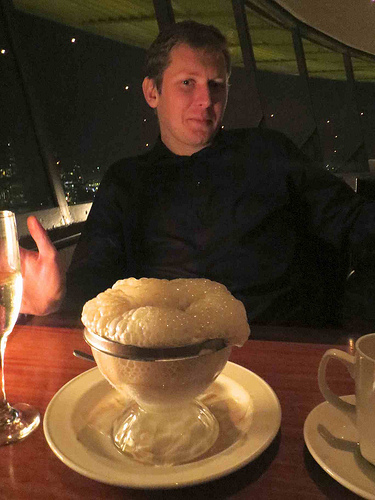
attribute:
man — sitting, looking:
[61, 16, 373, 327]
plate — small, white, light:
[304, 387, 374, 499]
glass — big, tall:
[0, 209, 44, 446]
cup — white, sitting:
[314, 332, 374, 463]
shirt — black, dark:
[59, 123, 372, 327]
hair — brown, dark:
[140, 19, 231, 92]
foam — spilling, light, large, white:
[75, 274, 250, 357]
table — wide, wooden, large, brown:
[2, 307, 371, 496]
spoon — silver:
[71, 347, 92, 367]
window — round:
[2, 1, 374, 229]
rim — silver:
[84, 317, 253, 362]